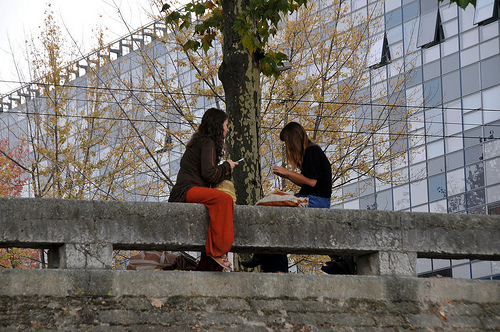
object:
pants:
[187, 183, 238, 260]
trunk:
[215, 36, 264, 272]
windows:
[425, 141, 448, 176]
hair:
[185, 107, 230, 167]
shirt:
[300, 145, 332, 200]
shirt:
[168, 130, 232, 202]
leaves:
[17, 175, 30, 184]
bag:
[255, 189, 310, 208]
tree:
[161, 0, 301, 274]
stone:
[0, 266, 499, 332]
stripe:
[210, 147, 215, 167]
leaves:
[200, 35, 211, 54]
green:
[203, 37, 208, 49]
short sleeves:
[306, 150, 320, 181]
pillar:
[58, 241, 116, 270]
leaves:
[347, 25, 362, 46]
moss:
[248, 89, 260, 109]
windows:
[384, 23, 403, 60]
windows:
[65, 90, 86, 125]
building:
[0, 0, 500, 279]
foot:
[210, 252, 234, 270]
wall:
[96, 203, 419, 271]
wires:
[0, 78, 500, 114]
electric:
[0, 110, 492, 141]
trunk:
[39, 245, 50, 268]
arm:
[290, 164, 331, 193]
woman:
[239, 120, 334, 270]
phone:
[228, 157, 245, 169]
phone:
[270, 164, 288, 174]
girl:
[169, 105, 240, 274]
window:
[366, 35, 391, 67]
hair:
[279, 119, 310, 170]